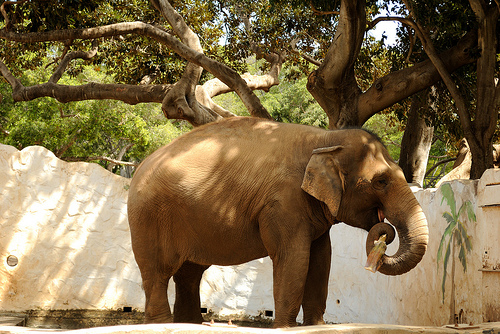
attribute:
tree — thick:
[371, 1, 498, 179]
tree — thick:
[305, 0, 496, 128]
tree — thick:
[396, 0, 466, 187]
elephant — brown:
[125, 118, 432, 332]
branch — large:
[122, 12, 326, 147]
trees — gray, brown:
[9, 35, 480, 172]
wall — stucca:
[1, 143, 498, 324]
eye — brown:
[371, 171, 383, 191]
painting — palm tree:
[437, 188, 481, 300]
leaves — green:
[68, 111, 124, 128]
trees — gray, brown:
[1, 1, 499, 188]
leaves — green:
[45, 96, 112, 146]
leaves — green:
[235, 2, 329, 63]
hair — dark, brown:
[289, 119, 378, 144]